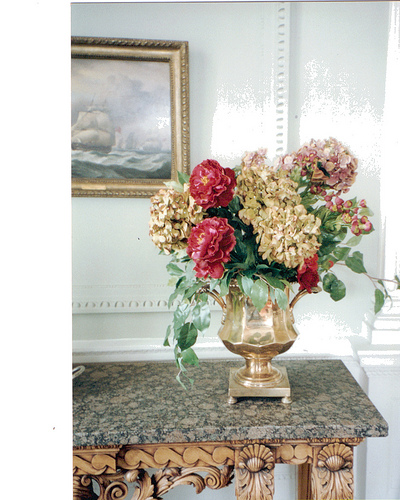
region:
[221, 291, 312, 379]
vase has a goldish color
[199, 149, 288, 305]
flowers are in the vase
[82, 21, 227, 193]
picture on the wall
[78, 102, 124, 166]
ship painted on the picture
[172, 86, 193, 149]
gold frame on the picture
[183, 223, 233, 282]
flower is red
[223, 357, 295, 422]
vase is sitting on a table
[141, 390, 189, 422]
table has a marble top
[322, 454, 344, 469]
shell in the wood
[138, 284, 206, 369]
leaves haning over the vase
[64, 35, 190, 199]
picture on wall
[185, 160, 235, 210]
red flower in vase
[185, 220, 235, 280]
red flower in vase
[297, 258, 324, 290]
red flower in vase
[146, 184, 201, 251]
gold flower in vase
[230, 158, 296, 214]
gold flower in vase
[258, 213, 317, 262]
gold flower in vase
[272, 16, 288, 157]
frame of picture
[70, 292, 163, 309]
frame of picture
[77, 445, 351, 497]
wood legs of table with marble top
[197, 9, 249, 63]
this is the wall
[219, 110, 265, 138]
the wall is white in color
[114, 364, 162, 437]
this is a table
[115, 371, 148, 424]
the table is made of marble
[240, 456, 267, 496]
the area is made of wood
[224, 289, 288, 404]
this is a vase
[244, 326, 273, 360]
the vase is golden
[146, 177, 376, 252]
these are some flowers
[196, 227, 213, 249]
the rose is red in color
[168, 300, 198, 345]
the leaves are green in color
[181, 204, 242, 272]
a red flower in a vase.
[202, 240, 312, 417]
a gold vase with flowers.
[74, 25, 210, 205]
a picture in a picture frame.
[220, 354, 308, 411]
the base of a gold vase.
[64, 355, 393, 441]
the top of a table.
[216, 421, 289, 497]
a leg on a table.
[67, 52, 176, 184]
a painting in a frame.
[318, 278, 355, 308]
a leaf in a vase.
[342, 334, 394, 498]
a piece of wood on a wall.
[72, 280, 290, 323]
moulding on a wall.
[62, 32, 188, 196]
a golden framed picture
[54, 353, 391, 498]
a marble and wood accent table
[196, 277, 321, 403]
a shinny gold vase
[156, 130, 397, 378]
red, pink and white flowers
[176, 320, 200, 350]
a single green leaf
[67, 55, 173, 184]
a paint picture of a boat in a rough sea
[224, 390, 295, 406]
the two front feet of a vase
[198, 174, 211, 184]
the yellow center of a flower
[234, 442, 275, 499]
carving in a wooden table leg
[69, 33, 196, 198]
a painted picture hanging on a wall